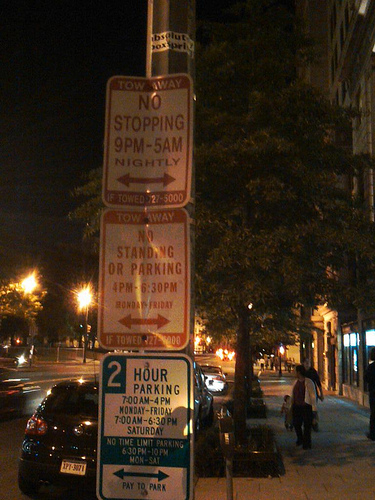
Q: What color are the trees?
A: Green.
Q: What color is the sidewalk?
A: Gray.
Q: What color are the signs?
A: White, red, orange, and blue.